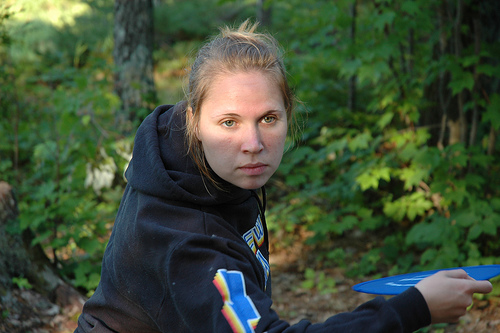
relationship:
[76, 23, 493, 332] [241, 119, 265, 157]
woman has a nose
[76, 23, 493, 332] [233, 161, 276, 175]
woman has a mouth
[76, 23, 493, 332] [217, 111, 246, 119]
woman has brow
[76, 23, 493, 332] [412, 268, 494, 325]
woman has a hand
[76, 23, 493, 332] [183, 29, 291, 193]
woman has a head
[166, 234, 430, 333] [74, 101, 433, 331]
sleeve on shirt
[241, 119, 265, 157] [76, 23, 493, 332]
nose on woman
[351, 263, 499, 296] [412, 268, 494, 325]
frisbee in hand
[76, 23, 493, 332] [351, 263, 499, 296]
woman with frisbee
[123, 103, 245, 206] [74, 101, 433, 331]
hood on shirt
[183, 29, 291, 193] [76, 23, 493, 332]
head of woman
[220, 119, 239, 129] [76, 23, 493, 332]
eye of woman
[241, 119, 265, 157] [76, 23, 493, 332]
nose of woman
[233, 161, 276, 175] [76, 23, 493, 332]
mouth of woman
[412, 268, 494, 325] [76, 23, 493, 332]
hand of woman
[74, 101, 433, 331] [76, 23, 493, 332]
shirt of woman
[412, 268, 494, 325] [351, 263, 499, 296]
hand has frisbee